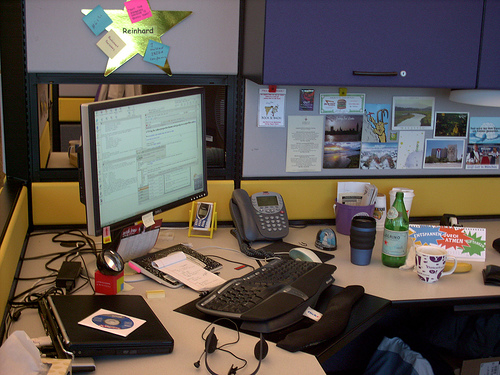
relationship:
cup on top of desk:
[415, 246, 457, 284] [1, 219, 499, 375]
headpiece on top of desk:
[194, 316, 269, 374] [1, 219, 499, 375]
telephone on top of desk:
[228, 187, 291, 243] [1, 219, 499, 375]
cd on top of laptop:
[79, 309, 146, 338] [47, 293, 175, 356]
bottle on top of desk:
[381, 190, 409, 269] [1, 219, 499, 375]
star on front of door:
[80, 0, 193, 79] [22, 0, 241, 75]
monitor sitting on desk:
[76, 86, 208, 238] [1, 219, 499, 375]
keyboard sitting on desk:
[194, 257, 338, 321] [1, 219, 499, 375]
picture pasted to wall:
[323, 113, 364, 170] [243, 78, 500, 179]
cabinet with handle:
[239, 0, 481, 89] [352, 69, 400, 77]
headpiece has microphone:
[194, 316, 269, 374] [193, 359, 201, 370]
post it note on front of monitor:
[142, 210, 156, 229] [76, 86, 208, 238]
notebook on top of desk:
[151, 250, 228, 293] [1, 219, 499, 375]